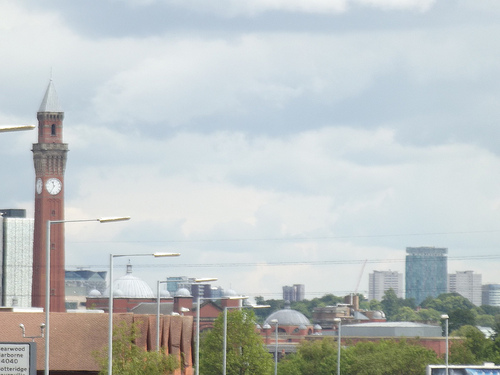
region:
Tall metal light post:
[35, 209, 63, 366]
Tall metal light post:
[103, 240, 179, 374]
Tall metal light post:
[151, 269, 228, 369]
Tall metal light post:
[194, 288, 251, 374]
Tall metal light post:
[222, 301, 270, 373]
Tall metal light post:
[260, 309, 292, 371]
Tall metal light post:
[313, 309, 352, 371]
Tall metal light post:
[428, 304, 463, 374]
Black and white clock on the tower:
[40, 173, 66, 194]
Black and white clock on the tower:
[28, 179, 51, 199]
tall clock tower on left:
[30, 109, 82, 324]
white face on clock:
[47, 171, 72, 208]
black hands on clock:
[40, 174, 60, 198]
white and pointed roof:
[40, 75, 70, 128]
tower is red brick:
[31, 179, 78, 345]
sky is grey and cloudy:
[137, 29, 324, 216]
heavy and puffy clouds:
[107, 2, 325, 210]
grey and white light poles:
[31, 201, 248, 371]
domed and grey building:
[252, 293, 324, 334]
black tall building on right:
[383, 230, 450, 300]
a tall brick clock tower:
[33, 68, 68, 309]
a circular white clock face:
[45, 177, 61, 195]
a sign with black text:
[0, 340, 31, 374]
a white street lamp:
[108, 250, 180, 373]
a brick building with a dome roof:
[261, 307, 312, 341]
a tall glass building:
[406, 244, 449, 302]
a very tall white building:
[366, 267, 403, 304]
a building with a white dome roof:
[88, 261, 153, 311]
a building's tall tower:
[39, 70, 63, 142]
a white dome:
[101, 258, 154, 300]